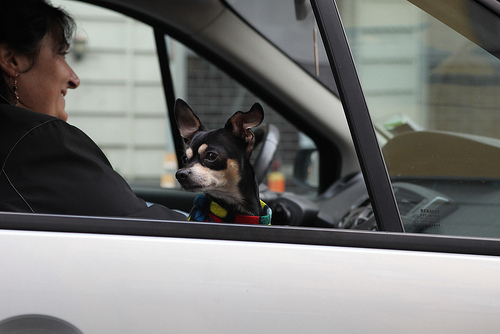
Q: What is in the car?
A: Dog.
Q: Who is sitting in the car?
A: Dog.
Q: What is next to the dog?
A: Glass window.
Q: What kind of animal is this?
A: Dog.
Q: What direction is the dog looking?
A: Left.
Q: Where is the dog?
A: Car.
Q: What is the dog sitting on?
A: Woman's lap.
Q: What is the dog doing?
A: Looking out of car window.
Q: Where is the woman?
A: Inside the car.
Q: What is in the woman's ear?
A: Earrings.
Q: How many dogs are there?
A: One.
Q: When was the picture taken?
A: Daytime.